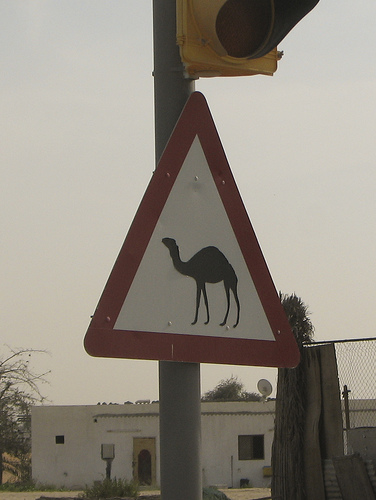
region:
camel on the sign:
[155, 224, 242, 334]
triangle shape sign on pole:
[48, 75, 308, 390]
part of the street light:
[132, 5, 323, 88]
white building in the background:
[32, 394, 326, 482]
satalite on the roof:
[244, 372, 290, 403]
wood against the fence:
[294, 330, 360, 494]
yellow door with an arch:
[119, 431, 158, 490]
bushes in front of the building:
[67, 469, 145, 498]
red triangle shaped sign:
[33, 72, 338, 355]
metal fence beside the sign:
[276, 314, 372, 491]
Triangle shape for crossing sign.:
[76, 84, 301, 372]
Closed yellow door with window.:
[131, 432, 160, 492]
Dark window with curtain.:
[235, 429, 269, 460]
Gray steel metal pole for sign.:
[149, 359, 212, 495]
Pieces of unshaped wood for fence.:
[268, 336, 374, 495]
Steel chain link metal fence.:
[265, 337, 375, 481]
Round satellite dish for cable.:
[252, 375, 277, 399]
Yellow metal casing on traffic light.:
[163, 4, 320, 86]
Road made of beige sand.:
[11, 480, 286, 497]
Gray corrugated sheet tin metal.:
[312, 449, 374, 495]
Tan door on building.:
[127, 439, 161, 497]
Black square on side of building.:
[49, 430, 89, 457]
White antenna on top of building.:
[257, 371, 276, 396]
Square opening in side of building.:
[233, 425, 266, 463]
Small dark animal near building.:
[235, 472, 257, 485]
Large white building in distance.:
[28, 381, 356, 484]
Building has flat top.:
[57, 396, 323, 417]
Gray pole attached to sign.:
[147, 351, 222, 496]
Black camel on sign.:
[157, 220, 257, 323]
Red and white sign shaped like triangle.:
[103, 238, 346, 350]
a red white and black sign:
[80, 88, 322, 374]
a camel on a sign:
[156, 224, 255, 327]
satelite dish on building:
[254, 375, 276, 406]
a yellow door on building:
[123, 428, 164, 497]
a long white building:
[22, 386, 374, 488]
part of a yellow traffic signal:
[174, 7, 297, 84]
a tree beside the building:
[0, 359, 29, 486]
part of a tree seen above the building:
[265, 283, 318, 358]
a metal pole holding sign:
[157, 280, 205, 494]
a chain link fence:
[291, 327, 369, 498]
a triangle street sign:
[63, 90, 313, 412]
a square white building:
[12, 386, 289, 493]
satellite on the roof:
[234, 374, 289, 406]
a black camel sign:
[156, 228, 246, 328]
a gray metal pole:
[127, 346, 243, 498]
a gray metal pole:
[143, 45, 183, 213]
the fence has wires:
[305, 331, 372, 489]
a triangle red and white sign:
[96, 136, 313, 435]